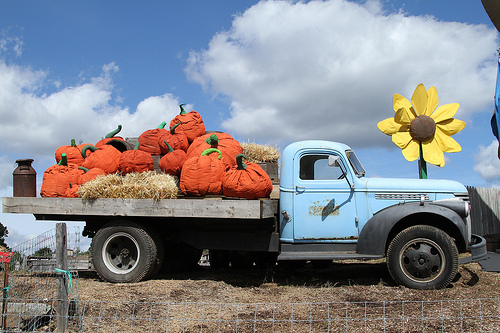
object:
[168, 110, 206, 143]
fake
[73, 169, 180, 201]
hay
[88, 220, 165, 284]
wheel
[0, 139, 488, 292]
truck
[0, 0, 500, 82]
sky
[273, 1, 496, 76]
cloud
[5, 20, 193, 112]
cloud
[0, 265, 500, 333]
field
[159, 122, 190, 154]
pumpkin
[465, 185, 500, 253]
fence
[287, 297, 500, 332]
fence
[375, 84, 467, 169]
fabric sunflower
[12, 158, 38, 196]
bucket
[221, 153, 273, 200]
pumpkin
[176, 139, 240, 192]
pumpkin